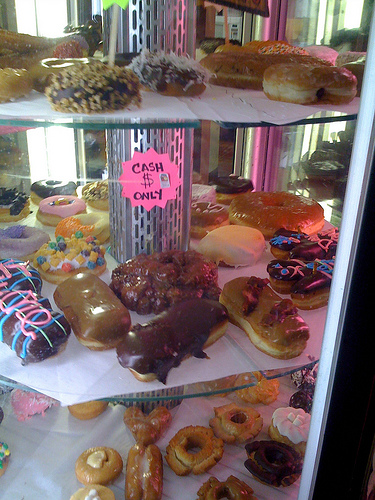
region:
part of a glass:
[131, 257, 149, 270]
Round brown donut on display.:
[174, 426, 212, 470]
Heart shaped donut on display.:
[120, 411, 178, 435]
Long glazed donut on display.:
[121, 450, 169, 495]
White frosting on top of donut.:
[276, 403, 310, 449]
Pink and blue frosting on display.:
[7, 290, 49, 341]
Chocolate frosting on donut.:
[67, 277, 113, 344]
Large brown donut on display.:
[129, 256, 207, 302]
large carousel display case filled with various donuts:
[2, 1, 370, 498]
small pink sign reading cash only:
[91, 143, 201, 233]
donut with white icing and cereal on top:
[31, 232, 108, 277]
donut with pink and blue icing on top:
[0, 251, 77, 367]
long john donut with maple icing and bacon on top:
[215, 269, 311, 352]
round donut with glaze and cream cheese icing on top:
[70, 445, 132, 484]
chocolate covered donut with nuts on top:
[29, 51, 146, 125]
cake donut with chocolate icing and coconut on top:
[120, 39, 216, 107]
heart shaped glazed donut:
[114, 404, 171, 445]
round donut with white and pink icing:
[267, 401, 315, 462]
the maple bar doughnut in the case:
[62, 275, 135, 347]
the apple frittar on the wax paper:
[112, 250, 219, 304]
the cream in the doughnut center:
[87, 449, 112, 469]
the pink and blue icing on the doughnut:
[2, 286, 56, 356]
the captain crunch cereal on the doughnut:
[36, 234, 104, 273]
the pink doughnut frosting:
[38, 194, 84, 212]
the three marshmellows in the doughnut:
[283, 410, 308, 427]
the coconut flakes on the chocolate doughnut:
[132, 44, 210, 90]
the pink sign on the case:
[116, 145, 186, 217]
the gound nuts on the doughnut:
[44, 60, 144, 120]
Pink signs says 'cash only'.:
[116, 144, 180, 209]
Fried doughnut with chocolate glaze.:
[240, 438, 302, 484]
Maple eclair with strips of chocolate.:
[218, 277, 310, 357]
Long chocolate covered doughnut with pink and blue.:
[0, 254, 70, 355]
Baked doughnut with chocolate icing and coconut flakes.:
[128, 54, 208, 97]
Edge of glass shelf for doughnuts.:
[0, 112, 203, 132]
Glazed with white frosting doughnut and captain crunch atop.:
[36, 230, 111, 283]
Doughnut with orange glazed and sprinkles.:
[52, 210, 112, 241]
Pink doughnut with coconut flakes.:
[11, 389, 52, 418]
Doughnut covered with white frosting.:
[203, 225, 265, 265]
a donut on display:
[234, 272, 292, 350]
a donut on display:
[205, 465, 243, 497]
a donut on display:
[257, 434, 296, 490]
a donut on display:
[167, 408, 216, 484]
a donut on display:
[213, 401, 260, 442]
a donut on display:
[264, 403, 327, 453]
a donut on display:
[125, 440, 162, 485]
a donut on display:
[83, 438, 123, 480]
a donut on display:
[144, 300, 204, 373]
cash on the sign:
[125, 161, 158, 173]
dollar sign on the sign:
[136, 168, 151, 188]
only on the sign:
[125, 191, 162, 204]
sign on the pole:
[120, 147, 171, 208]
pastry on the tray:
[72, 445, 118, 481]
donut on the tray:
[141, 413, 221, 474]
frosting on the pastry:
[10, 300, 48, 324]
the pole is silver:
[146, 15, 172, 40]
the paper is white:
[25, 474, 63, 491]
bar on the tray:
[235, 281, 297, 350]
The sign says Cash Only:
[114, 145, 181, 209]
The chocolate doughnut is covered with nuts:
[41, 56, 141, 116]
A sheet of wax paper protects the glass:
[0, 181, 329, 406]